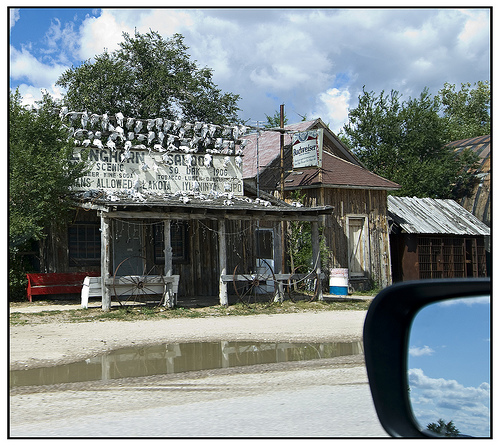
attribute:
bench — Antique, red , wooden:
[24, 270, 106, 301]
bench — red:
[81, 275, 185, 307]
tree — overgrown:
[8, 86, 85, 295]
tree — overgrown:
[53, 27, 249, 132]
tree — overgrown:
[258, 101, 294, 133]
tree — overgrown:
[343, 90, 476, 195]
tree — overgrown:
[434, 76, 491, 139]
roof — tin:
[386, 195, 491, 240]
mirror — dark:
[362, 275, 487, 437]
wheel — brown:
[221, 254, 298, 308]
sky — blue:
[422, 322, 472, 375]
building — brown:
[376, 191, 468, 279]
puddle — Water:
[9, 330, 370, 397]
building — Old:
[25, 73, 481, 338]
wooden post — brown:
[264, 100, 311, 303]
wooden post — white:
[218, 105, 342, 255]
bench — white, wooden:
[82, 273, 179, 308]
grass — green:
[19, 298, 360, 320]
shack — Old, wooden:
[272, 148, 399, 293]